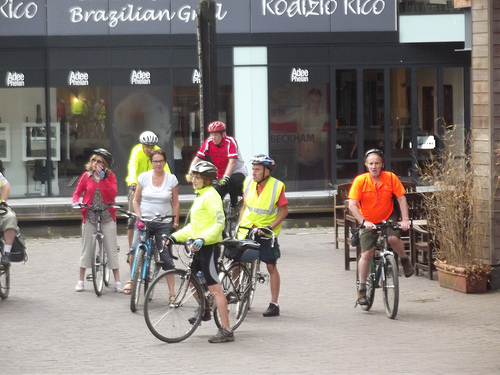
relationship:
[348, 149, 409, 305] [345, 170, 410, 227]
biker wears shirt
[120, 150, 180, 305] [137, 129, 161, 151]
biker wears helmet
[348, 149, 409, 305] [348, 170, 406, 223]
biker wears orange shirt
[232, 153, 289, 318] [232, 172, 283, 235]
biker wears neon jacket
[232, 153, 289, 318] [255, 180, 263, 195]
biker wears orange t-shirt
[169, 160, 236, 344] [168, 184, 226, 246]
biker wears tops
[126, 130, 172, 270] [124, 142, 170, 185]
bikes wears jacket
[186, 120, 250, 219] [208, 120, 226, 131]
biker wears helmet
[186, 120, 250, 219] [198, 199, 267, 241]
biker on bike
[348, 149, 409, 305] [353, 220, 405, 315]
biker rides bike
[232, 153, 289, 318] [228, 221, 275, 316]
biker rides bike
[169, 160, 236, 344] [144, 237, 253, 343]
biker rides bicycle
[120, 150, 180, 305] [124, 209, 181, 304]
biker rides bike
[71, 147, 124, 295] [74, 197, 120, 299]
biker rides bike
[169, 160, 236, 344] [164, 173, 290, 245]
biker wear tops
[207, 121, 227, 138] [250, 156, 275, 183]
helmet on head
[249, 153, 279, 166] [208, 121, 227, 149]
helmet on head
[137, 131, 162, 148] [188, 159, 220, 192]
helmet on head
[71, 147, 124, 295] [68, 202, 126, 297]
biker on bike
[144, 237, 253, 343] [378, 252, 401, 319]
bicycle has wheel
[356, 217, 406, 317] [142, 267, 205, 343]
bicycle has wheel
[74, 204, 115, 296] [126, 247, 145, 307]
bicycle has wheel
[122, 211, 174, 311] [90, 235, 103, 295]
bicycle has wheel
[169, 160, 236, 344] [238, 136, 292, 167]
biker wears helmet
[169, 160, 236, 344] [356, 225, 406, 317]
biker on bicycle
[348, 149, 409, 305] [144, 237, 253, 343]
biker on bicycle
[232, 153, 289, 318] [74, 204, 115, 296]
biker on bicycle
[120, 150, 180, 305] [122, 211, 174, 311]
biker on bicycle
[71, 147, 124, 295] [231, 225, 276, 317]
biker on bicycle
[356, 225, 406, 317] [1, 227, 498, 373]
bicycle on ground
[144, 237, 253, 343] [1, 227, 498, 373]
bicycle on ground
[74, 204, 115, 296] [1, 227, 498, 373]
bicycle on ground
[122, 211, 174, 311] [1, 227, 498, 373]
bicycle on ground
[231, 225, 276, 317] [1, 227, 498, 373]
bicycle on ground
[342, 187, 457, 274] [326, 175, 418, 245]
table near chairs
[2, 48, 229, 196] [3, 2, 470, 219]
window on storefront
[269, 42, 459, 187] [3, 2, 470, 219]
window on storefront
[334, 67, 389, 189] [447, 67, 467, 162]
furniture inside glass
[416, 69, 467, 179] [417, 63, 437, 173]
furniture inside glass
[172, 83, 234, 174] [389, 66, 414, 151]
furniture inside glass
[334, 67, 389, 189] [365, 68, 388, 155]
furniture inside glass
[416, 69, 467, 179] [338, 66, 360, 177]
furniture inside glass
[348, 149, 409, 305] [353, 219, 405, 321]
biker riding a bicycle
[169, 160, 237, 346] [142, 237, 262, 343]
biker standing over bike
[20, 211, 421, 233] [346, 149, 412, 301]
water behind person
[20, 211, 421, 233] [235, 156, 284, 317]
water behind person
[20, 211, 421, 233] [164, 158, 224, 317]
water behind person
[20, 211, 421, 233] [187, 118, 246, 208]
water behind person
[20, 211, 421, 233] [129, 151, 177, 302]
water behind person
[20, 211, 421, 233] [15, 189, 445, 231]
water inside canal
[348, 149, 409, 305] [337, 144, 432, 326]
biker wearing shirt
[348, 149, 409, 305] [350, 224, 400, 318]
biker riding a bike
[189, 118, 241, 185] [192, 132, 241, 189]
biker wearing shirt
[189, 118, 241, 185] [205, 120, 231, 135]
biker wearing helmet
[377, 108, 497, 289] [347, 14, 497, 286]
plant in front of building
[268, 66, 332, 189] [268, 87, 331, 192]
advertising poster showing david beckham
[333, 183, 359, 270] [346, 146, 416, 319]
chairs behind biker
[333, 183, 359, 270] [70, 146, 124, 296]
chairs behind biker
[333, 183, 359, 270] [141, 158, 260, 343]
chairs behind biker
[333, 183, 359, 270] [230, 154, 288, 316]
chairs behind biker